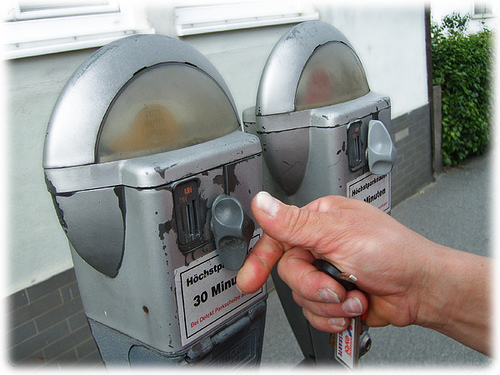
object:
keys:
[310, 254, 367, 368]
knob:
[208, 190, 257, 269]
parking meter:
[38, 32, 268, 366]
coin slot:
[185, 195, 200, 243]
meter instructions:
[174, 226, 271, 347]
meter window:
[92, 59, 241, 161]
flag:
[105, 103, 186, 155]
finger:
[231, 235, 293, 296]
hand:
[237, 188, 401, 335]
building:
[13, 22, 452, 235]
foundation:
[11, 273, 93, 360]